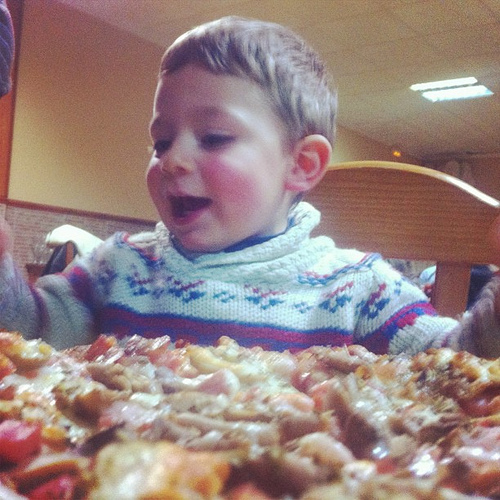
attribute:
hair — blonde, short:
[217, 18, 293, 49]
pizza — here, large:
[102, 362, 290, 441]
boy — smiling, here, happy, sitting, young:
[72, 16, 409, 334]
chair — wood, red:
[321, 147, 485, 259]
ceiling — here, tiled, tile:
[364, 2, 447, 40]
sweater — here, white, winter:
[123, 259, 333, 338]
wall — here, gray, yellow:
[62, 40, 135, 72]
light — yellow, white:
[434, 73, 483, 113]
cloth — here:
[48, 222, 60, 227]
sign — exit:
[397, 145, 472, 169]